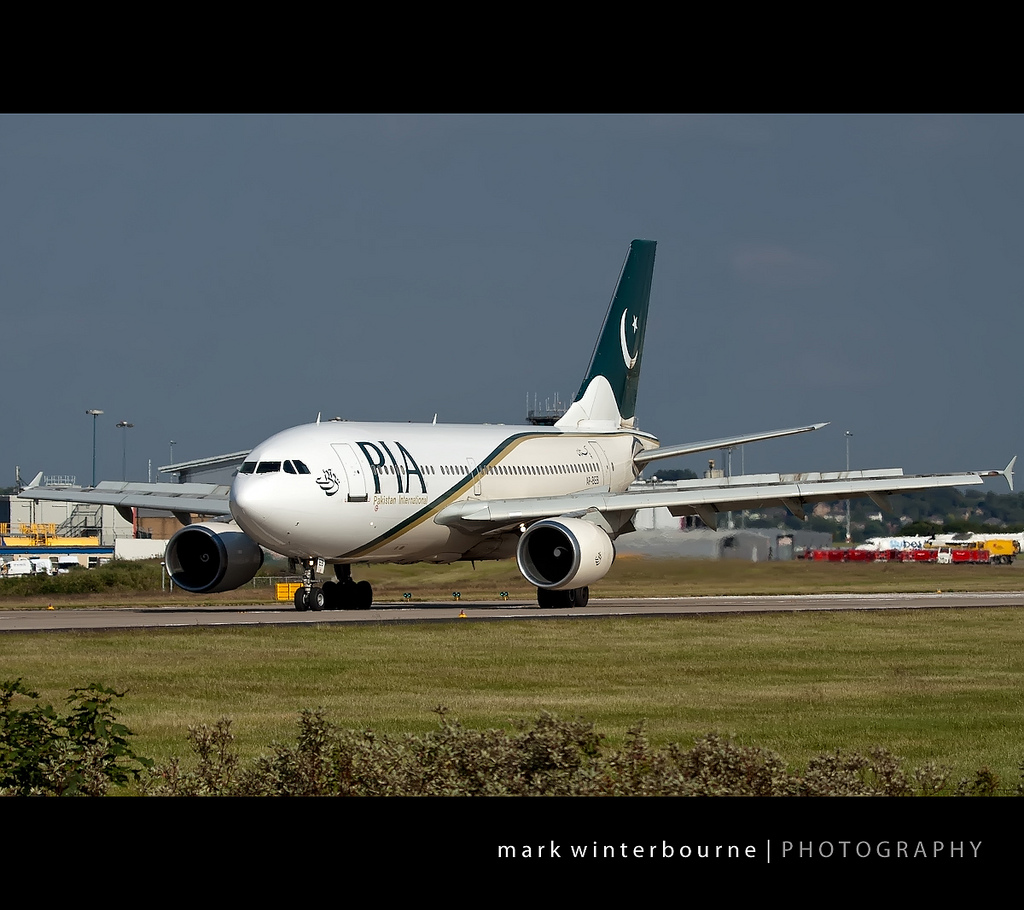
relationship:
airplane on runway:
[144, 420, 698, 602] [18, 592, 1023, 647]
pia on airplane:
[359, 437, 445, 504] [144, 420, 698, 602]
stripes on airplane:
[454, 418, 581, 497] [144, 420, 698, 602]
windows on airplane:
[425, 454, 623, 484] [144, 420, 698, 602]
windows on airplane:
[425, 454, 623, 484] [15, 237, 1024, 617]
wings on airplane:
[462, 429, 990, 521] [144, 420, 698, 602]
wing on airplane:
[32, 473, 228, 518] [144, 420, 698, 602]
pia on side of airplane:
[359, 437, 445, 504] [144, 420, 698, 602]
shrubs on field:
[60, 555, 182, 592] [449, 545, 1004, 601]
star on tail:
[633, 319, 642, 335] [598, 234, 659, 421]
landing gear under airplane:
[271, 568, 357, 612] [15, 237, 1024, 617]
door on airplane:
[330, 437, 379, 509] [144, 420, 698, 602]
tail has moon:
[598, 234, 659, 421] [618, 311, 637, 371]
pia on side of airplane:
[359, 437, 445, 504] [15, 237, 1024, 617]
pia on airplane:
[359, 437, 445, 504] [15, 237, 1024, 617]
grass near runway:
[151, 632, 974, 772] [18, 592, 1023, 647]